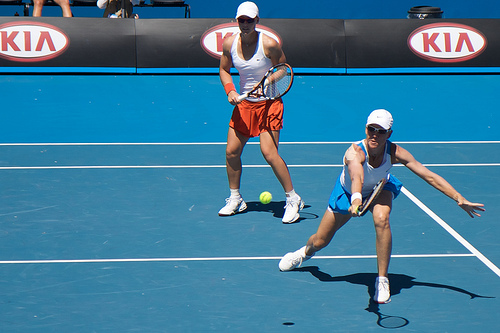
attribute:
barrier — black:
[1, 17, 498, 74]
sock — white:
[284, 186, 299, 200]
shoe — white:
[282, 196, 307, 224]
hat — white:
[363, 106, 401, 138]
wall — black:
[37, 16, 484, 68]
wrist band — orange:
[349, 189, 354, 206]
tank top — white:
[228, 31, 281, 101]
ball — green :
[255, 187, 279, 207]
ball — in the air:
[260, 191, 272, 203]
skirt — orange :
[228, 92, 283, 137]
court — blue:
[5, 73, 498, 330]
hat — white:
[233, 0, 259, 22]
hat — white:
[363, 106, 393, 131]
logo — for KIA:
[0, 18, 72, 62]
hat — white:
[352, 107, 397, 132]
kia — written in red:
[419, 29, 477, 55]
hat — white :
[341, 101, 418, 141]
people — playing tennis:
[213, 0, 303, 228]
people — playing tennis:
[276, 105, 485, 305]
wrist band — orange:
[218, 82, 240, 96]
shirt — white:
[229, 27, 280, 102]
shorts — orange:
[196, 100, 326, 154]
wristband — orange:
[223, 80, 238, 92]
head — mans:
[366, 107, 396, 149]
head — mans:
[233, 2, 262, 34]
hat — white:
[228, 1, 260, 22]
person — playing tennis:
[217, 2, 301, 222]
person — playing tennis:
[273, 106, 489, 304]